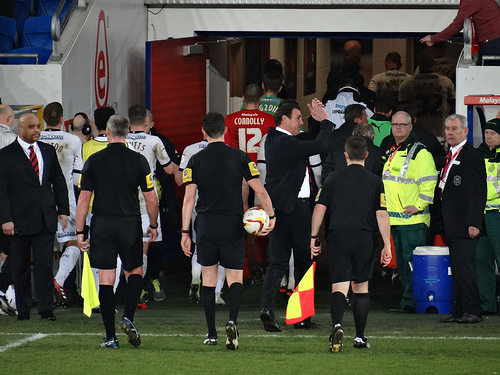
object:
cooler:
[407, 245, 453, 315]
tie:
[27, 145, 39, 178]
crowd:
[0, 39, 500, 354]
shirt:
[36, 128, 84, 210]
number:
[237, 127, 262, 153]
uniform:
[238, 95, 304, 133]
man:
[259, 97, 336, 333]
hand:
[307, 98, 325, 122]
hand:
[310, 99, 329, 122]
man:
[308, 134, 393, 354]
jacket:
[381, 131, 441, 229]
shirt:
[381, 140, 437, 227]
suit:
[0, 137, 71, 314]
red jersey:
[222, 108, 275, 164]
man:
[475, 118, 500, 316]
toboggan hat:
[482, 117, 499, 135]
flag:
[285, 261, 317, 325]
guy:
[179, 111, 275, 350]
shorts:
[193, 213, 248, 271]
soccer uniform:
[181, 140, 261, 270]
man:
[173, 125, 228, 306]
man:
[430, 114, 488, 325]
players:
[0, 58, 500, 353]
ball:
[242, 206, 271, 236]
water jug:
[408, 245, 453, 315]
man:
[222, 83, 275, 285]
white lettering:
[231, 112, 264, 154]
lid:
[413, 246, 451, 256]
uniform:
[79, 142, 154, 271]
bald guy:
[0, 112, 72, 320]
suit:
[431, 141, 488, 318]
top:
[380, 138, 440, 229]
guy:
[380, 110, 438, 314]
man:
[75, 114, 159, 349]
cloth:
[79, 251, 100, 319]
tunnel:
[59, 0, 148, 116]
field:
[0, 297, 500, 375]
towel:
[80, 251, 101, 318]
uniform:
[313, 163, 387, 285]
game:
[0, 0, 500, 375]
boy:
[309, 136, 393, 354]